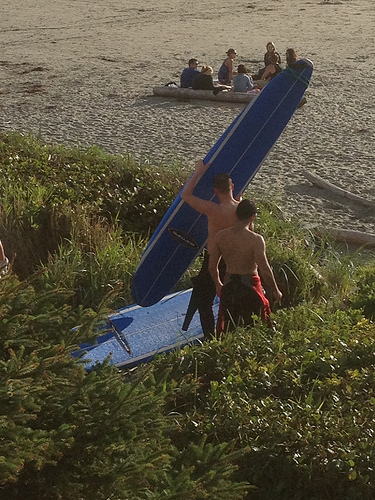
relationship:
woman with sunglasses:
[192, 66, 217, 91] [228, 50, 240, 55]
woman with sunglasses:
[213, 45, 239, 87] [191, 61, 199, 66]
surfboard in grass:
[143, 77, 365, 386] [0, 128, 375, 500]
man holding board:
[208, 197, 281, 330] [129, 58, 314, 308]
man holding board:
[180, 160, 255, 340] [129, 58, 314, 308]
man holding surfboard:
[180, 157, 256, 341] [130, 57, 317, 310]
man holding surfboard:
[191, 185, 299, 346] [52, 55, 313, 322]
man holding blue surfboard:
[180, 157, 256, 341] [131, 53, 320, 307]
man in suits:
[208, 197, 284, 338] [198, 263, 219, 299]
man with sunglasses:
[208, 197, 284, 338] [190, 60, 196, 66]